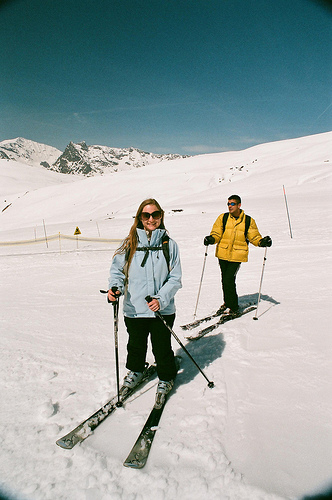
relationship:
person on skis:
[107, 196, 184, 391] [53, 357, 185, 471]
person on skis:
[201, 192, 273, 315] [180, 297, 260, 342]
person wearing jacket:
[107, 196, 184, 391] [106, 227, 184, 320]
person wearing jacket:
[201, 192, 273, 315] [210, 210, 264, 265]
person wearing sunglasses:
[107, 196, 184, 391] [137, 210, 166, 222]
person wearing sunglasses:
[201, 192, 273, 315] [226, 200, 241, 207]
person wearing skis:
[107, 196, 184, 391] [53, 357, 185, 471]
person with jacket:
[201, 192, 273, 315] [210, 210, 264, 265]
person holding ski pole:
[107, 196, 184, 391] [143, 295, 217, 388]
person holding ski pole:
[107, 196, 184, 391] [99, 284, 128, 407]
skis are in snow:
[53, 357, 185, 471] [1, 131, 332, 500]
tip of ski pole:
[207, 382, 217, 389] [143, 295, 217, 388]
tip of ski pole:
[115, 399, 126, 410] [99, 284, 128, 407]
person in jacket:
[107, 196, 184, 391] [106, 227, 184, 320]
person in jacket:
[201, 192, 273, 315] [210, 210, 264, 265]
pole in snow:
[281, 183, 295, 243] [1, 131, 332, 500]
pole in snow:
[41, 216, 53, 250] [1, 131, 332, 500]